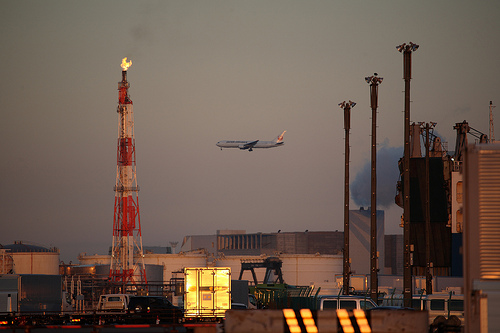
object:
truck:
[180, 264, 232, 323]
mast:
[337, 99, 355, 303]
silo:
[12, 251, 60, 275]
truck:
[63, 293, 138, 326]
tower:
[101, 56, 152, 297]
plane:
[216, 130, 288, 152]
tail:
[272, 129, 287, 142]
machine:
[232, 255, 293, 308]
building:
[183, 230, 341, 255]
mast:
[393, 41, 418, 306]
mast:
[363, 72, 384, 302]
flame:
[118, 56, 133, 72]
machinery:
[449, 119, 489, 160]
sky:
[1, 1, 497, 264]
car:
[127, 295, 183, 317]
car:
[318, 295, 380, 311]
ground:
[10, 299, 494, 331]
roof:
[313, 294, 374, 303]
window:
[217, 142, 219, 144]